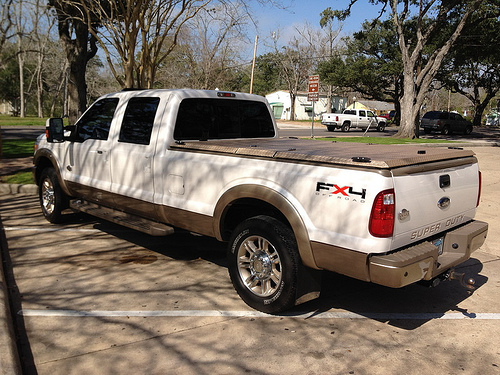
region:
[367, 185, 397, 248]
left brake light on truck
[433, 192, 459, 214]
ford logo on truck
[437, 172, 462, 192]
black handle on truck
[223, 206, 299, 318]
rear black tire on truck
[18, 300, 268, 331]
white line painted on ground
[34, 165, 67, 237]
front left tire on truck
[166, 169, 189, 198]
gas tank on left side of truck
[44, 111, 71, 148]
left rear view mirror on truck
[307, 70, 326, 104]
sign on the pole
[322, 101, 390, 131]
white truck in background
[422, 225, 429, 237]
white letter on truck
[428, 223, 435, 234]
white letter on truck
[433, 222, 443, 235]
white letter on truck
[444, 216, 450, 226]
white letter on truck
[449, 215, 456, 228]
white letter on truck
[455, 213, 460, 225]
white letter on truck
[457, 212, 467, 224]
white letter on truck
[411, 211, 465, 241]
white letters on truck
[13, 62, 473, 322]
pick up truck parked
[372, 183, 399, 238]
red light on a truck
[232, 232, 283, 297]
chrome rim on a truck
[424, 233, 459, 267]
license plate on the truck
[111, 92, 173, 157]
black tints on a window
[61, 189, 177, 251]
stepping board on a truck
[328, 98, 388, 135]
white truck on the street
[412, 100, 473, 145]
jeep parked on the street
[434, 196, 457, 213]
ford emblem on the truck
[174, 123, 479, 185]
cover on a pick up truck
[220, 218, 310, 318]
wheel of a truck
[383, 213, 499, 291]
bumper of a truck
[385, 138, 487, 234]
rear of a truck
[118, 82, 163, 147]
window of a truck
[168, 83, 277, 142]
window of a truck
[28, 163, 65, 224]
wheel of a truck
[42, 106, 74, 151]
mirro of a truck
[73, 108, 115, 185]
door of a truck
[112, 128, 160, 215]
door of a truck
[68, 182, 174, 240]
step way of a truck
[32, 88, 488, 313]
the truck in a parking lot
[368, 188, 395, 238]
the light on the truck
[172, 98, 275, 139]
the window on the back of the truck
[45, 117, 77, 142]
the side mirror on the truck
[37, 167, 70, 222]
the front tire on the truck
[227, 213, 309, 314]
the back tire on the truck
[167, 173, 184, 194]
the cover to the gas tank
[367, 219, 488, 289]
the bumper on the back of the truck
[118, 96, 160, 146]
the passenger window behind the driver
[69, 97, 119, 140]
the window on the driver's side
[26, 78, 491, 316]
a large white pickup truck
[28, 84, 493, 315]
a big white truck